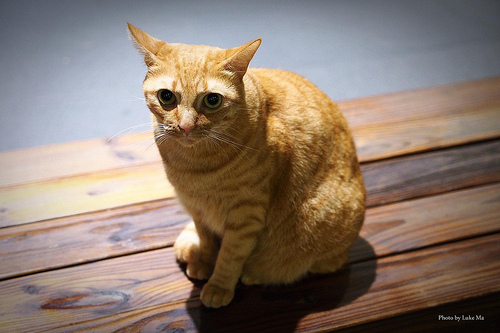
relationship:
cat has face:
[127, 22, 366, 308] [144, 68, 238, 147]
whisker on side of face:
[203, 128, 264, 155] [144, 68, 238, 147]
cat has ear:
[127, 22, 366, 308] [219, 38, 261, 86]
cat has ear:
[127, 22, 366, 308] [127, 22, 168, 62]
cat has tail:
[127, 22, 366, 308] [173, 219, 203, 263]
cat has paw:
[127, 22, 366, 308] [183, 257, 215, 279]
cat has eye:
[127, 22, 366, 308] [202, 92, 223, 110]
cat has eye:
[127, 22, 366, 308] [155, 89, 178, 107]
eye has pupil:
[202, 92, 223, 110] [207, 93, 219, 105]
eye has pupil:
[155, 89, 178, 107] [161, 89, 173, 100]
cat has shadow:
[127, 22, 366, 308] [177, 233, 378, 331]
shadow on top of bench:
[177, 233, 378, 331] [2, 76, 499, 331]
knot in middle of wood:
[40, 292, 125, 308] [1, 180, 500, 329]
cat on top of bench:
[127, 22, 366, 308] [2, 76, 499, 331]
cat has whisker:
[127, 22, 366, 308] [203, 128, 264, 155]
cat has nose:
[127, 22, 366, 308] [178, 124, 196, 134]